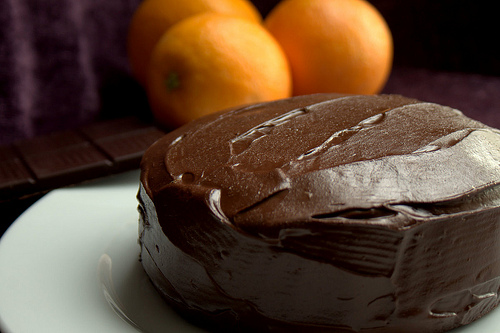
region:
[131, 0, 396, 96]
three oranges out of focus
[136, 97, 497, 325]
a cake covered with chocolate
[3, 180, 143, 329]
part of a white plate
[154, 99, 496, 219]
the top of the cake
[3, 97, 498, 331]
the cake is on the plate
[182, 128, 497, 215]
this color is dark brown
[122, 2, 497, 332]
three oranges and a chocolate cake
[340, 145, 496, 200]
the light reflected on the cake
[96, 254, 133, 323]
some light reflected on the plate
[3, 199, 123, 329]
the plate is white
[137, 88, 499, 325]
The chocolate cake on the white plate.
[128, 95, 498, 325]
The chocolate icing on the cake.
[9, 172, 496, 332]
The white plate the cake is on.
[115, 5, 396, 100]
The three oranges on the table.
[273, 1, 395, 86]
The orange on the right.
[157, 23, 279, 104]
The orange on the left.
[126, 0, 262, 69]
The orange in the back.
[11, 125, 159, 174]
The bars of chocolate to the left of the oranges.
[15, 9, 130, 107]
The purple table cloth.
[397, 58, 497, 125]
The purple table cloth on the right.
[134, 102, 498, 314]
The chocolate cake on the plate.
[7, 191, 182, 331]
The white plate the cake is on.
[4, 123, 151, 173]
The pieces of chocolate to the left of the oranges.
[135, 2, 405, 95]
The oranges on the table.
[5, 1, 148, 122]
The left corner of the table.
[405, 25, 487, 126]
The right corner of the table.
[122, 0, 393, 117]
three large oranges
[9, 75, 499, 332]
chocolate cake on a white plate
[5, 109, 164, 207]
chocolate candy bars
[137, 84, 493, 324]
cake with chocolate frosting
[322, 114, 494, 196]
light shining on chocolate frosting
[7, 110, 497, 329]
round with plate with a chocolate cake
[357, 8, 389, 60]
light reflecting on orange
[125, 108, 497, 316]
cake with smooth chocolate frosting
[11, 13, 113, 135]
purple fabric in the background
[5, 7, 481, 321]
photograph of chocolate cake and oranges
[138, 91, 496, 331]
homemade cake with chocolate frosting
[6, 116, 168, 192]
bar of chocolate used for baking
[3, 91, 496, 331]
chocolate cake on white plate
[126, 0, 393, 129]
three unpeeled oranges beside cake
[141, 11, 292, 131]
one of three oranges beside chocolate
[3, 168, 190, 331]
white plate holding cake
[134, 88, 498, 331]
uncut chocolate cake on plate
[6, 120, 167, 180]
baking chocolate in sections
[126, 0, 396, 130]
three oranges beside white plate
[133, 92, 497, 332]
swirled and smoothed chocolat frosting on cake